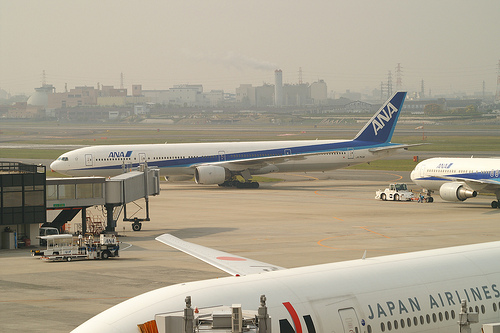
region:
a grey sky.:
[152, 2, 270, 64]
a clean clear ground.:
[231, 178, 370, 243]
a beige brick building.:
[165, 76, 208, 108]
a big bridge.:
[333, 95, 387, 110]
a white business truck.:
[25, 205, 126, 268]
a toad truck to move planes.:
[370, 180, 445, 215]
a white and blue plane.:
[405, 150, 495, 205]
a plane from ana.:
[50, 97, 401, 179]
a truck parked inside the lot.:
[36, 220, 59, 240]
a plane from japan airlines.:
[70, 235, 495, 330]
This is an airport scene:
[13, 41, 489, 322]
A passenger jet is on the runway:
[39, 88, 424, 190]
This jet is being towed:
[375, 150, 498, 217]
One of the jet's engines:
[188, 159, 240, 194]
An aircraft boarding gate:
[44, 160, 172, 217]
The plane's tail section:
[339, 83, 431, 167]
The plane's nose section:
[48, 147, 88, 176]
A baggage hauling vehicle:
[31, 224, 129, 280]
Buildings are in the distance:
[26, 62, 356, 120]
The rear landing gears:
[221, 173, 265, 196]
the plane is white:
[368, 254, 411, 310]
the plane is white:
[316, 306, 351, 326]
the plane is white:
[313, 286, 351, 320]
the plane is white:
[315, 276, 381, 326]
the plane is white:
[333, 257, 370, 316]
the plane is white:
[343, 259, 380, 327]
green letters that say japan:
[351, 290, 421, 330]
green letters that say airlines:
[427, 276, 497, 324]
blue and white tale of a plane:
[332, 83, 417, 180]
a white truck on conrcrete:
[352, 175, 412, 227]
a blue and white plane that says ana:
[77, 78, 416, 179]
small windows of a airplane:
[347, 297, 462, 331]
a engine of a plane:
[423, 174, 475, 229]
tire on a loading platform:
[117, 151, 181, 240]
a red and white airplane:
[139, 229, 466, 330]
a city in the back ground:
[1, 64, 338, 122]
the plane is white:
[316, 325, 328, 331]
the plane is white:
[324, 254, 394, 329]